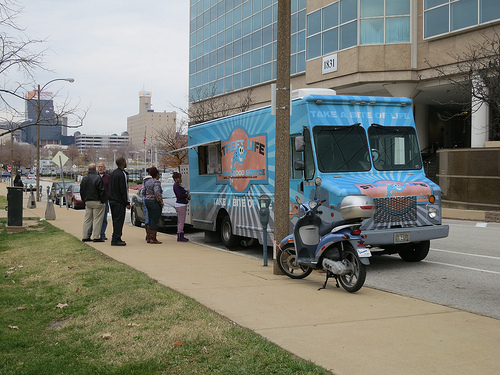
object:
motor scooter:
[275, 193, 374, 293]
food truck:
[186, 87, 451, 263]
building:
[186, 0, 499, 223]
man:
[107, 156, 133, 246]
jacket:
[105, 168, 135, 206]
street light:
[271, 1, 290, 278]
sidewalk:
[0, 182, 499, 374]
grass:
[1, 197, 330, 374]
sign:
[320, 52, 340, 75]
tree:
[0, 0, 93, 136]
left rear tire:
[218, 213, 233, 249]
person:
[171, 170, 191, 241]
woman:
[145, 164, 165, 244]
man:
[79, 161, 108, 243]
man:
[95, 160, 110, 240]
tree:
[409, 29, 499, 147]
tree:
[142, 117, 189, 179]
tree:
[163, 73, 259, 125]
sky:
[0, 1, 193, 135]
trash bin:
[5, 185, 24, 229]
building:
[74, 133, 131, 162]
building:
[18, 97, 63, 144]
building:
[125, 89, 177, 150]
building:
[0, 121, 29, 144]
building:
[38, 138, 66, 146]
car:
[130, 181, 180, 230]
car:
[65, 182, 87, 212]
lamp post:
[34, 84, 43, 203]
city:
[0, 86, 190, 184]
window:
[358, 15, 385, 48]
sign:
[214, 125, 268, 198]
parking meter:
[255, 192, 272, 267]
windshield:
[311, 123, 372, 173]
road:
[359, 214, 499, 323]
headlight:
[428, 210, 438, 220]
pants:
[172, 203, 188, 234]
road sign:
[49, 150, 72, 168]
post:
[58, 155, 71, 211]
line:
[428, 247, 499, 261]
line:
[420, 256, 500, 275]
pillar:
[471, 74, 487, 151]